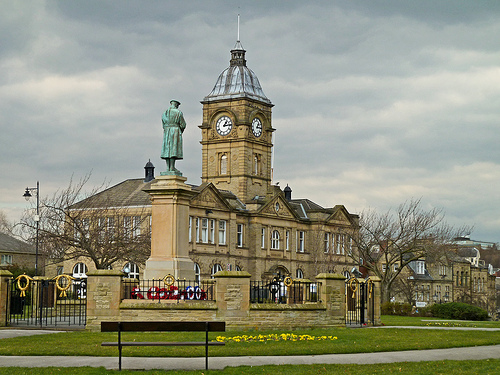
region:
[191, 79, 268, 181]
Two clocks on a tower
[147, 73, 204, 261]
Statue on a pillar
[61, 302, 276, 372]
Bench on the side of a small walkway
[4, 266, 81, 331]
Gold colored wreaths decorating a gate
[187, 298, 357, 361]
Yellow flowers in center of grass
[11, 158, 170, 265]
Tree with no branches outside of a building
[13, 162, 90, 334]
Tall street lamp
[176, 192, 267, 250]
Upstairs windows in a building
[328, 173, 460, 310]
Tree with no leaves in front of a building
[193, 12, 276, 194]
Two large clocks in a building tower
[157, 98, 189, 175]
a statue on top of the tower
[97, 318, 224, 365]
a bench next to the sidewalk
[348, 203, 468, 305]
the bare tree next to the building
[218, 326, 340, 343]
the yellow flowers sitting in the grass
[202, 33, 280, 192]
the clocktower on top of the building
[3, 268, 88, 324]
the gate with golden decorations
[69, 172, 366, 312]
a big fancy building with a clocktower above it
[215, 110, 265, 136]
the clock near the top of the buildings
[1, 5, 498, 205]
the sky filled with somewhat dark clouds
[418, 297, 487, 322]
a bush off to the side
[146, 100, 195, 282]
a statue is on a pedestal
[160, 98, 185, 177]
the statute is green in color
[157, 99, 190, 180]
the statute is weathered in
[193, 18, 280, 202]
a tower is atop a building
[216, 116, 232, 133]
a clock is on the tower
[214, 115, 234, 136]
the clock face is white in color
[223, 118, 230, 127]
the dials are black in color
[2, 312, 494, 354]
the grass is green in color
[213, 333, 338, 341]
the plants are yellow in color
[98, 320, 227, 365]
a bench is in front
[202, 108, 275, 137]
two clocks on either side of the building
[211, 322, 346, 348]
yellow flowers in the grass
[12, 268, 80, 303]
wreathes hanging on the fence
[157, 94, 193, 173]
green statue of a person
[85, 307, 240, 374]
black bench on the grass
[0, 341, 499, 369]
walking path cutting through the grass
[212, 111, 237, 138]
clock indicating it's about 1:15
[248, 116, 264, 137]
black and white clock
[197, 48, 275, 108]
top of the clock tower is blue and gray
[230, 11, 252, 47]
pole on top of the tower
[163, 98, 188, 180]
the statute is on it's back side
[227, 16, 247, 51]
a spire is on the tower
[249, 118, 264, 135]
a clock is on the tower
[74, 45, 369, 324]
the building is made of brick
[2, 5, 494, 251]
the sky is very cloudy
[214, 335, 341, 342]
the flowers are yellow in color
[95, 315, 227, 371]
the bench is made of wood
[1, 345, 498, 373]
a pathway runs across the way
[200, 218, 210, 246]
the window has a white frame